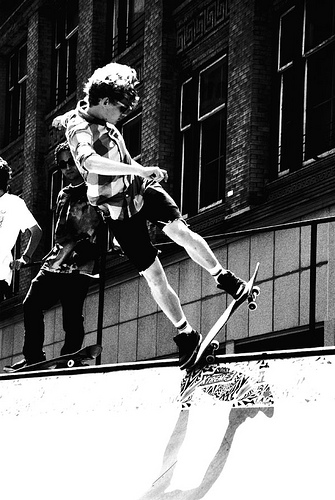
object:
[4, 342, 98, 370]
skateboard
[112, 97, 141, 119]
glasses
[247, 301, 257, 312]
wheel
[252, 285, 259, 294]
wheel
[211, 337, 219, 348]
wheel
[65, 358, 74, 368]
wheel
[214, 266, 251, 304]
shoe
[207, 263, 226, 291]
sock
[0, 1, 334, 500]
park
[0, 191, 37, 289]
t shirt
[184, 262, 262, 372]
skateboard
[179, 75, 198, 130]
window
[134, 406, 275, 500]
shadow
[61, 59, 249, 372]
men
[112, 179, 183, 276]
shorts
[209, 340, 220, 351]
wheels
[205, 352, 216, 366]
wheels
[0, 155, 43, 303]
man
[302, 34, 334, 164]
big windows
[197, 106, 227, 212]
big windows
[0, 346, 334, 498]
skate wall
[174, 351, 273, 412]
print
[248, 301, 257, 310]
wheel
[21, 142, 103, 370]
skateboarder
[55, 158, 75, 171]
sunglasses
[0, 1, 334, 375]
wall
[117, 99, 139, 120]
sunglasses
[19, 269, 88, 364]
pants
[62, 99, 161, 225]
shirt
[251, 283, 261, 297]
wheels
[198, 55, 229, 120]
window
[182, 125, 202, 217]
windows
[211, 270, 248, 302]
feet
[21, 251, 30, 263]
bracelet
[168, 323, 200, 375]
skating shoe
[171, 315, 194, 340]
sock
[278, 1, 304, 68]
window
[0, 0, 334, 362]
building.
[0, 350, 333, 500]
ramp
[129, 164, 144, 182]
wrist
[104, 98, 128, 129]
man's face